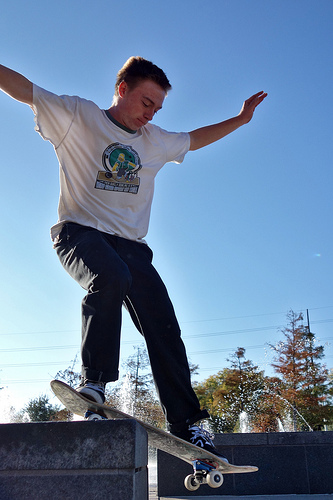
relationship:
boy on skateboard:
[3, 49, 272, 462] [48, 376, 261, 487]